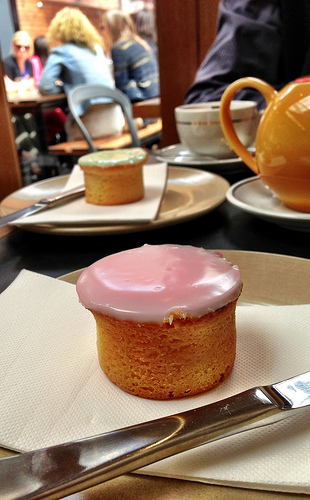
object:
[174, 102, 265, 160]
cup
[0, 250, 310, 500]
plate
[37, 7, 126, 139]
person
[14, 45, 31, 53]
glasses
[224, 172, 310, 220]
saucer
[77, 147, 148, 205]
cupcake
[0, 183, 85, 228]
butterknife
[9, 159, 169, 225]
napkin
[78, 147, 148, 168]
frosting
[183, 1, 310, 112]
person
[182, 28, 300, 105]
arm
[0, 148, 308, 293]
tabble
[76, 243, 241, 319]
icing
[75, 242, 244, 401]
cupcake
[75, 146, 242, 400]
two cupcakes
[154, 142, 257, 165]
saucer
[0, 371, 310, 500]
knife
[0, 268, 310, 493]
napkin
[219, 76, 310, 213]
kettle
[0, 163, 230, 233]
plate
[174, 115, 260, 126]
gold line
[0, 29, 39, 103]
woman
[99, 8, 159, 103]
woman